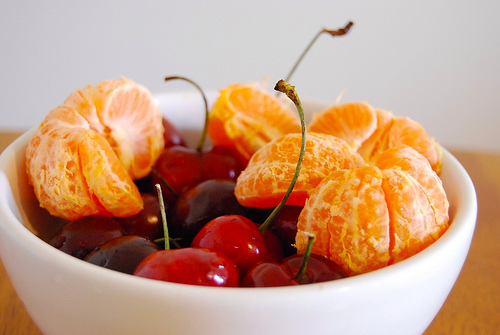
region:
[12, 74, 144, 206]
orange is orange and white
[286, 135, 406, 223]
orange is orange and white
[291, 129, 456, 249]
orange is orange and white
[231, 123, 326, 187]
orange is orange and white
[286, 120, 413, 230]
orange is orange and white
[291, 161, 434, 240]
orange is orange and white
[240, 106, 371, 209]
orange is orange and white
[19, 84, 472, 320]
Fruit in a bowl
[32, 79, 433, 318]
Fruit in a white bowl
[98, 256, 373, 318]
the edge of a white bowl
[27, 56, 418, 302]
Cherries in a white bowl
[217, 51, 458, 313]
oranges in a white bowl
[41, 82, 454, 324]
Cherries and oranges in a white bowl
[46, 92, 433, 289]
Cherries and oranges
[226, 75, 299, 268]
A cherry with a stem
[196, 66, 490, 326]
A bowl of fruit on a table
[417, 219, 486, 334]
A bowl on a wood table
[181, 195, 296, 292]
cherry is vibrant red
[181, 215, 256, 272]
cherry is vibrant red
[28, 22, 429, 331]
fruit is in a bowl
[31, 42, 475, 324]
cherries in a bowl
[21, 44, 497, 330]
oranges are in a bowl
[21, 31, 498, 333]
oranges and cherries in a bowl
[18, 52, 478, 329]
fruit in a white bowl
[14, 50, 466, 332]
the bowl is white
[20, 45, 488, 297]
the oranges are peeled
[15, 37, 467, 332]
a white bowl of fruit on a table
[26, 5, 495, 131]
the walls are white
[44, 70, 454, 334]
the cherries are red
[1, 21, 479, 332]
a bowl of tasty looking fresh fruit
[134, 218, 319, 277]
a few red cherries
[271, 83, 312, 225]
the stem of a cherry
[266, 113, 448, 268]
a couple tangerines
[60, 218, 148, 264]
a couple dark red cherries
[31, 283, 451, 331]
a white ceramic bowl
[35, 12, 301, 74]
a white wall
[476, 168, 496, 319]
a wooden table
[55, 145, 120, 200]
the pith of a tangerine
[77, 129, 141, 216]
a tangerine segment